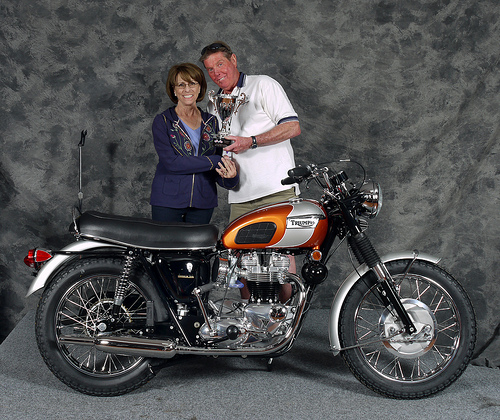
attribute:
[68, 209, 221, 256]
seat — leather, black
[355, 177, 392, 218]
light — chrome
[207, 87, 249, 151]
trophy — silver, award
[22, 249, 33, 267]
brake light — red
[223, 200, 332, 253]
gas tank — orange, silver